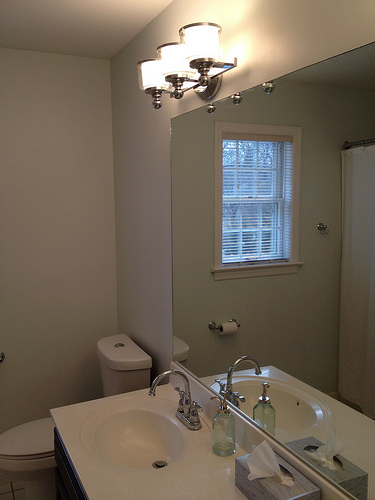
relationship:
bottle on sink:
[209, 393, 238, 458] [49, 361, 375, 498]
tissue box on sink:
[236, 440, 320, 500] [49, 361, 375, 498]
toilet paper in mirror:
[207, 318, 241, 338] [169, 42, 375, 499]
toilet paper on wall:
[207, 318, 241, 338] [1, 48, 114, 431]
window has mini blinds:
[212, 119, 304, 282] [223, 138, 286, 262]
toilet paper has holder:
[207, 318, 241, 338] [208, 318, 242, 331]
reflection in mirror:
[208, 114, 375, 499] [169, 42, 375, 499]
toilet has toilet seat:
[1, 333, 153, 499] [1, 414, 57, 455]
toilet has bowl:
[1, 333, 153, 499] [1, 456, 58, 486]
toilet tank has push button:
[99, 333, 153, 396] [114, 342, 126, 349]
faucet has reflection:
[149, 368, 204, 433] [215, 354, 263, 407]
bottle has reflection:
[209, 393, 238, 458] [252, 382, 277, 440]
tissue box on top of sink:
[236, 440, 320, 500] [49, 361, 375, 498]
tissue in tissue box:
[246, 439, 284, 481] [236, 440, 320, 500]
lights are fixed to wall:
[136, 23, 239, 108] [109, 2, 375, 393]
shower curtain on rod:
[338, 145, 375, 414] [342, 134, 375, 150]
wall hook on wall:
[316, 221, 332, 237] [1, 48, 114, 431]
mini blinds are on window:
[223, 138, 286, 262] [212, 119, 304, 282]